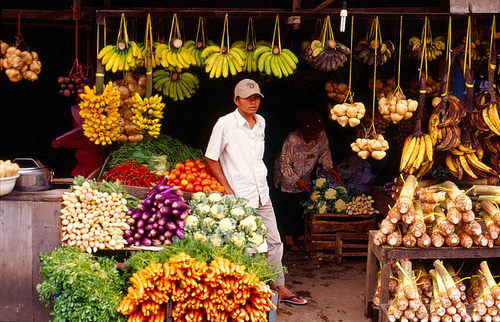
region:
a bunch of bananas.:
[249, 41, 311, 90]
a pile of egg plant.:
[121, 183, 198, 250]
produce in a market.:
[334, 120, 402, 168]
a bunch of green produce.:
[26, 248, 146, 317]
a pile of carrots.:
[118, 226, 280, 320]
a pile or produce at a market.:
[349, 207, 498, 308]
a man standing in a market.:
[197, 53, 313, 303]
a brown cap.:
[225, 76, 274, 104]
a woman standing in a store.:
[268, 104, 342, 270]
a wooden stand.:
[0, 188, 77, 319]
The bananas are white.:
[388, 121, 497, 169]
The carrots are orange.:
[108, 239, 250, 319]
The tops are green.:
[114, 227, 301, 284]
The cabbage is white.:
[204, 194, 303, 281]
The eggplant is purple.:
[107, 171, 178, 254]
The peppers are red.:
[98, 152, 162, 184]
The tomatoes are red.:
[155, 144, 242, 203]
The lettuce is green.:
[34, 237, 131, 321]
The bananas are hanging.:
[75, 9, 485, 91]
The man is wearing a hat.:
[202, 72, 286, 129]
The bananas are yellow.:
[393, 107, 498, 160]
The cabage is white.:
[189, 187, 271, 272]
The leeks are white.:
[373, 172, 495, 315]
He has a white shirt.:
[204, 119, 284, 211]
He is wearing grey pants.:
[225, 169, 303, 308]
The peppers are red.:
[73, 148, 169, 201]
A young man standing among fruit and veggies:
[194, 60, 349, 267]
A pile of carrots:
[121, 252, 264, 320]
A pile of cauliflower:
[180, 186, 262, 244]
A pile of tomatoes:
[163, 157, 226, 194]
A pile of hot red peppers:
[96, 150, 168, 190]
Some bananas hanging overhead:
[92, 37, 294, 88]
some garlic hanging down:
[327, 87, 414, 159]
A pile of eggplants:
[135, 186, 182, 248]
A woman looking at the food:
[279, 110, 333, 234]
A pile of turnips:
[53, 175, 128, 251]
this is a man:
[228, 81, 282, 181]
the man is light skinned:
[213, 159, 221, 184]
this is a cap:
[241, 77, 254, 92]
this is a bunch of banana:
[263, 45, 290, 70]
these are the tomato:
[181, 155, 201, 188]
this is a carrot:
[171, 250, 188, 262]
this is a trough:
[0, 176, 19, 191]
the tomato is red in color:
[186, 167, 201, 182]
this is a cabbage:
[217, 207, 234, 227]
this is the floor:
[317, 290, 348, 317]